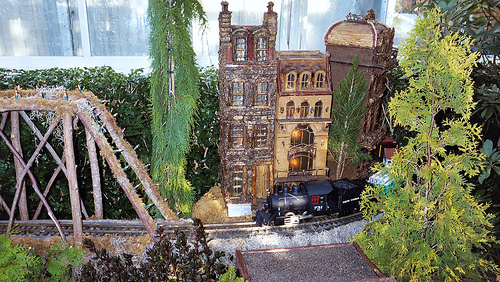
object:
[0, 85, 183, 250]
structure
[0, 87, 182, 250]
bridge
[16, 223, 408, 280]
ground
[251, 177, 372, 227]
model train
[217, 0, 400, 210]
model building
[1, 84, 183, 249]
overhang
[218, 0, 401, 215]
building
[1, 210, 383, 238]
tracks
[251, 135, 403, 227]
engine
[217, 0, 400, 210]
mansion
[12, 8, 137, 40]
white cloud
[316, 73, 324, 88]
window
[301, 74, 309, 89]
window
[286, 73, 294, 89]
window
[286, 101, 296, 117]
window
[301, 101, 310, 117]
window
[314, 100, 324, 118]
window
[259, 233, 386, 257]
floor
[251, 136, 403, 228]
train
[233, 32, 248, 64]
window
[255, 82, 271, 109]
windows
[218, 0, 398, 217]
house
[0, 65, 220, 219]
green bushes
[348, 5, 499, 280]
tree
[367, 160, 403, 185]
pipes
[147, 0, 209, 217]
tree